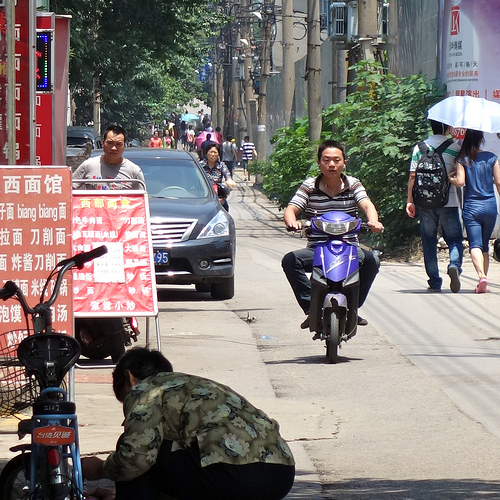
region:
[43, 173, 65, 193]
white foreign righting on red sign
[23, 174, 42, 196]
white foreign righting on red sign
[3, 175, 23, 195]
white foreign righting on red sign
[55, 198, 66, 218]
white foreign righting on red sign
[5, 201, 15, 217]
white foreign righting on red sign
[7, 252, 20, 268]
white foreign righting on red sign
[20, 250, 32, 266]
white foreign righting on red sign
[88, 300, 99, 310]
white foreign righting on red sign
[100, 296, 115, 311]
white foreign righting on red sign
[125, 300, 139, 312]
white foreign righting on red sign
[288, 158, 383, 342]
a man on a blue scooter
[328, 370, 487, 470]
grey asphalt of the road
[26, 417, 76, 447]
orange plate with white lettering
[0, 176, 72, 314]
red sign with white lettering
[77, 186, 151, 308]
red sign with white and yellow lettering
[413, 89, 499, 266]
two people walking under an umbrella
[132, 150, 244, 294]
a black car parked on the road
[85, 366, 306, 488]
a woman in a floral shirt crouching down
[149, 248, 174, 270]
blue license plate with white lettering on the car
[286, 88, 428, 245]
large green plant growing next to the building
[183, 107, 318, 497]
Busy narrow street.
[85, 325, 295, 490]
Lady fixing her bike.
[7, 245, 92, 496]
The lady's bike is blue.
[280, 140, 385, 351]
A young man riding a motorcycle on the street.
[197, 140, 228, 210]
Lady riding a red motorcycle.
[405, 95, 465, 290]
Young man walking and holding an umbrella.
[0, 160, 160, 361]
Store signs on the sidewalk.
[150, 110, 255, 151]
People walking on the street.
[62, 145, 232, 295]
Black car parked on the sidewalk.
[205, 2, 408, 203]
Electrical poles alongside of the busy street.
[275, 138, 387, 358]
Man driving a scooter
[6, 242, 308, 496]
a person working on there bike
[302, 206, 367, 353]
blue and black scooter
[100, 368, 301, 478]
tan, grey and white shirt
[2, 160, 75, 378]
a red sign with white symbols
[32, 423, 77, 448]
little red lisence plate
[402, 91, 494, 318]
two people walking under the umbrella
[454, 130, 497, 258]
a woman wearing all shiny blue outfit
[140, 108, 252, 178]
group of people walking in the road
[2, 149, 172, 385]
two red signs on the sidewalk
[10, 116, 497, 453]
Picture taken outdoors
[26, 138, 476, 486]
picture taken during the day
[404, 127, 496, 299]
people are walking on the street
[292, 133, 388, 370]
a man is riding a moped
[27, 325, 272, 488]
a man is leaning next to a bike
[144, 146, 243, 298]
a car is parked on the side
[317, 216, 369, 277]
the moped is blue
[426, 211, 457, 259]
the man wears jeans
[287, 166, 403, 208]
the man has a short sleeved shirt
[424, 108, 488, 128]
the man holds an umbrella